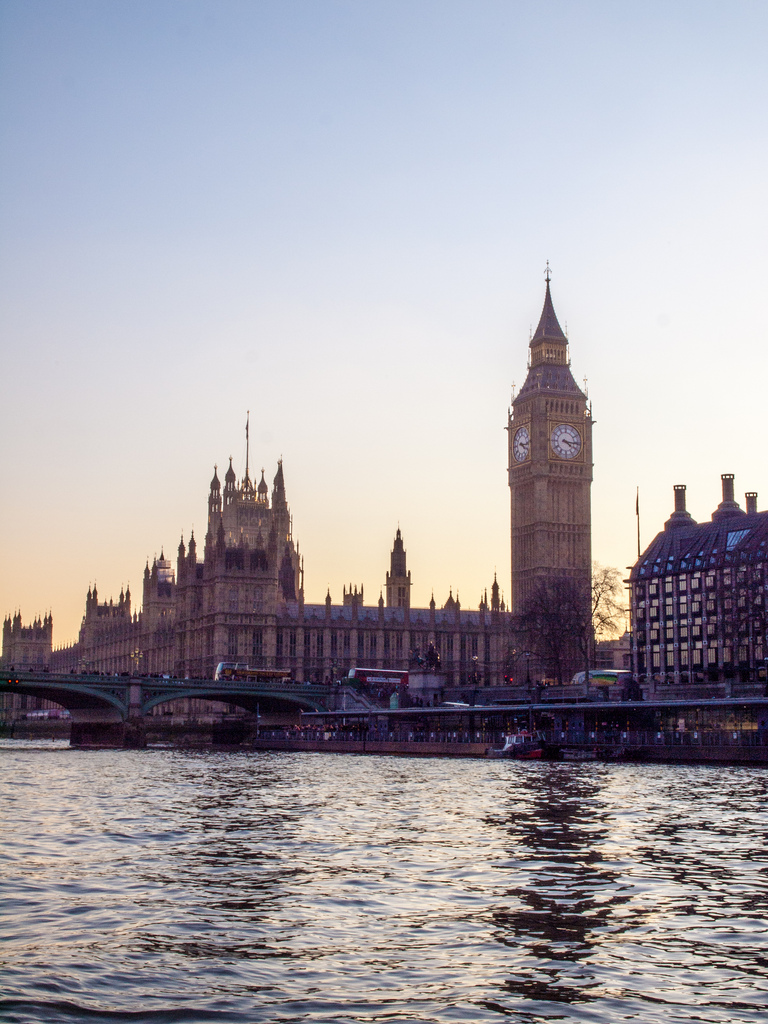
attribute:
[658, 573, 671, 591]
window — glass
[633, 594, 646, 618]
window — glass